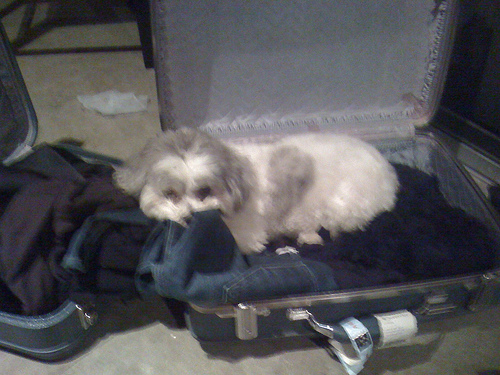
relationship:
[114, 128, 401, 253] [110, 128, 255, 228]
dog has head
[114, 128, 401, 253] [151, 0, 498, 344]
dog inside suitcase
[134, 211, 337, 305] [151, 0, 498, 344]
blue jeans inside suitcase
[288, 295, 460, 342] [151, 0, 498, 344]
handle attached to suitcase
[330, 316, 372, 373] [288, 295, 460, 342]
tag attached to handle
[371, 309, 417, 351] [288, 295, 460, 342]
tag attached to handle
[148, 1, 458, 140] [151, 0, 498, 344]
top of suitcase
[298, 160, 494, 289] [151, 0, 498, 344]
clothing inside suitcase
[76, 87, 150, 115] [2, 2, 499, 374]
tissue on top of floor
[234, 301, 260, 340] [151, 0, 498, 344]
lock attached to suitcase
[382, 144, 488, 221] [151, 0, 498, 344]
lining inside suitcase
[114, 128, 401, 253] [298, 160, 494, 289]
dog on top of clothing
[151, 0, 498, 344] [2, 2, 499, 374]
suitcase on top of floor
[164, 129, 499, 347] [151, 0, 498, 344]
bottom of suitcase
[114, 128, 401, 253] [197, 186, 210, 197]
dog has left eye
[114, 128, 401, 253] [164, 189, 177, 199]
dog has right eye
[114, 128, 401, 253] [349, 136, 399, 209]
dog has backside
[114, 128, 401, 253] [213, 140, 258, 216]
dog has right ear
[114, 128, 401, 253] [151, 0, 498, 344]
dog sleeping in suitcase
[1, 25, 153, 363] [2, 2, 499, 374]
suitcase on top of floor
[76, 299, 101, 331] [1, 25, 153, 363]
clasp attached to suitcase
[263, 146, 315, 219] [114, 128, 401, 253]
spot located on dog